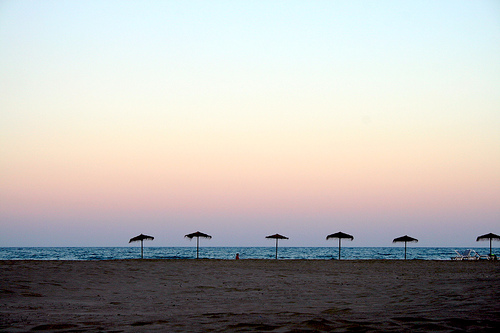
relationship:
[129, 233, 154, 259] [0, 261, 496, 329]
parasol on beach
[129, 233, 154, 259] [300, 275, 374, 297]
parasol on beach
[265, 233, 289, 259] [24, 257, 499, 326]
parasol on beach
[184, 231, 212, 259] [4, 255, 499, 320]
parasol on beach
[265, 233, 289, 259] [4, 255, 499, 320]
parasol on beach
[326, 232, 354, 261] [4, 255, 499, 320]
parasol on beach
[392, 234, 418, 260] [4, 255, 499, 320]
parasol on beach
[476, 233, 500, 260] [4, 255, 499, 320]
parasol on beach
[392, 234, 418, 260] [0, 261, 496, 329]
parasol on beach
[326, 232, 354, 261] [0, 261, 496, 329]
parasol on beach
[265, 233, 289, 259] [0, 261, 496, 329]
parasol on beach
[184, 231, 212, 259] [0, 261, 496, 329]
parasol on beach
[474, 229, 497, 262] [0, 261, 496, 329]
umbrella on beach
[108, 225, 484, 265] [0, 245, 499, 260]
parasols in front of ocean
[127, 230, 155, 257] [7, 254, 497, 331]
parasol on beach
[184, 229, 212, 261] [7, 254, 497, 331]
parasol on beach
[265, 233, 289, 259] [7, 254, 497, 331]
parasol on beach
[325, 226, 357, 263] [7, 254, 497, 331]
parasol on beach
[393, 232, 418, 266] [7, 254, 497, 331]
parasol on beach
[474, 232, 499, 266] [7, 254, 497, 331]
parasol on beach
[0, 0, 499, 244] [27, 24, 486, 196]
sky covering background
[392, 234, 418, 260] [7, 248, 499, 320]
parasol line beach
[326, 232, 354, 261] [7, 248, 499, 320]
parasol line beach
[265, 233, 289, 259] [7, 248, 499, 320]
parasol line beach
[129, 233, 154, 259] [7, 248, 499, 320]
parasol line beach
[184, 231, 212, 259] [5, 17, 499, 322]
parasol on beach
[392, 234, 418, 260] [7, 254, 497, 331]
parasol on beach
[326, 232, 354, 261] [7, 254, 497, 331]
parasol on beach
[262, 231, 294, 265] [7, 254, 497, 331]
parasol on beach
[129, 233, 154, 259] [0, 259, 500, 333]
parasol in beach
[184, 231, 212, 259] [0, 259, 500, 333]
parasol in beach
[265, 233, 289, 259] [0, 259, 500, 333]
parasol in beach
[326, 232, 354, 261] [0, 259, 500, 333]
parasol in beach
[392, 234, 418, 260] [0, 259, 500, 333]
parasol in beach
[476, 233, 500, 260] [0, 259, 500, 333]
parasol in beach